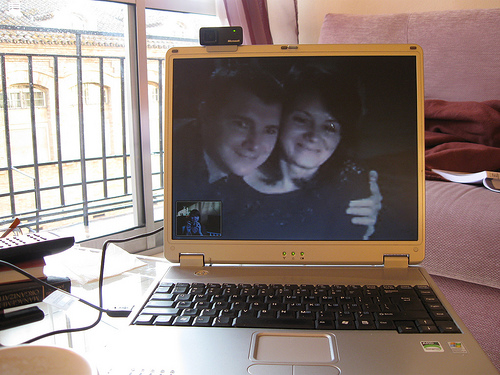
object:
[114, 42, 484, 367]
laptop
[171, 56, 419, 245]
screensaver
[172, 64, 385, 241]
couple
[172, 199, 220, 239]
photo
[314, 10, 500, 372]
area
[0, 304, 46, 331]
piled books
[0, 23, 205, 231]
fencing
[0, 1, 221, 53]
roof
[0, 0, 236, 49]
tiling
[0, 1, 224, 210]
building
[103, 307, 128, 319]
plug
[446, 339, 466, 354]
logo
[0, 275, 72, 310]
book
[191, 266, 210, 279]
button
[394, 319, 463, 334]
set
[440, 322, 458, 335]
key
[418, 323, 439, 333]
key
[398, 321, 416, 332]
key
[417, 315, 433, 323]
key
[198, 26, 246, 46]
webcam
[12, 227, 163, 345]
cable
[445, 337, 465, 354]
sticker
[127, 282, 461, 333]
keyboard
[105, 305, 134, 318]
drive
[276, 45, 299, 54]
logo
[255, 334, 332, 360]
pad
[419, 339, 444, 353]
stickers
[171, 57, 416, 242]
screen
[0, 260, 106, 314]
cable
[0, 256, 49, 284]
books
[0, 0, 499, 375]
room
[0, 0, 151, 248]
windows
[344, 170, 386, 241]
hand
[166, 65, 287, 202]
man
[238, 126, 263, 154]
nose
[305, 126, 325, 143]
nose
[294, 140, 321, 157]
mouth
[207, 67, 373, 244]
people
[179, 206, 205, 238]
girl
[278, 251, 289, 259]
light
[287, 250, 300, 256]
light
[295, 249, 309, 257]
light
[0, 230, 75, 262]
remote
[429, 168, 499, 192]
book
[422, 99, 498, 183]
blanket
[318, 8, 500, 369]
sofa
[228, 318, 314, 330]
keys